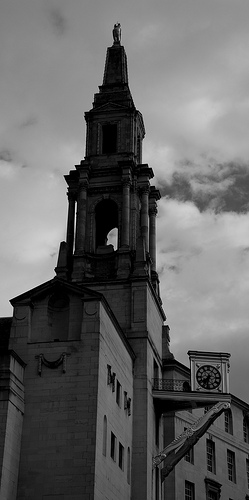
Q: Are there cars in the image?
A: No, there are no cars.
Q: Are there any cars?
A: No, there are no cars.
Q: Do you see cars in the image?
A: No, there are no cars.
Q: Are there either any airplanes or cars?
A: No, there are no cars or airplanes.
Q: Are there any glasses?
A: No, there are no glasses.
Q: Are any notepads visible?
A: No, there are no notepads.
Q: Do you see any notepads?
A: No, there are no notepads.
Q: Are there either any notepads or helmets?
A: No, there are no notepads or helmets.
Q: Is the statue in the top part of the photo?
A: Yes, the statue is in the top of the image.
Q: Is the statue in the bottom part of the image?
A: No, the statue is in the top of the image.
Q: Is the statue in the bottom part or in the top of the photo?
A: The statue is in the top of the image.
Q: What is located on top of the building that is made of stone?
A: The statue is on top of the tower.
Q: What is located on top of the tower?
A: The statue is on top of the tower.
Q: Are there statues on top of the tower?
A: Yes, there is a statue on top of the tower.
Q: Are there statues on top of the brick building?
A: Yes, there is a statue on top of the tower.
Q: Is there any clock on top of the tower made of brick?
A: No, there is a statue on top of the tower.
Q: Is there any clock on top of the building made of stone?
A: No, there is a statue on top of the tower.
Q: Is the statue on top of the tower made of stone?
A: Yes, the statue is on top of the tower.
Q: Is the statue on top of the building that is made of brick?
A: Yes, the statue is on top of the tower.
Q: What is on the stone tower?
A: The statue is on the tower.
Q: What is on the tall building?
A: The statue is on the tower.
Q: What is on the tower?
A: The statue is on the tower.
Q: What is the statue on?
A: The statue is on the tower.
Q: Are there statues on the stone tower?
A: Yes, there is a statue on the tower.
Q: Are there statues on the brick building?
A: Yes, there is a statue on the tower.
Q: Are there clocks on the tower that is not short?
A: No, there is a statue on the tower.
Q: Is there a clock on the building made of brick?
A: No, there is a statue on the tower.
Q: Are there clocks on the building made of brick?
A: No, there is a statue on the tower.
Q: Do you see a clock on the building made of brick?
A: No, there is a statue on the tower.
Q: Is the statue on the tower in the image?
A: Yes, the statue is on the tower.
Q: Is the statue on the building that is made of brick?
A: Yes, the statue is on the tower.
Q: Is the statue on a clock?
A: No, the statue is on the tower.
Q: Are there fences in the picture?
A: Yes, there is a fence.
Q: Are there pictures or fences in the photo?
A: Yes, there is a fence.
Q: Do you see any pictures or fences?
A: Yes, there is a fence.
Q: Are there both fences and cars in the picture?
A: No, there is a fence but no cars.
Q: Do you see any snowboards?
A: No, there are no snowboards.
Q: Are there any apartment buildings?
A: No, there are no apartment buildings.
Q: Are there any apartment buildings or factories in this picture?
A: No, there are no apartment buildings or factories.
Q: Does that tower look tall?
A: Yes, the tower is tall.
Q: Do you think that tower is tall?
A: Yes, the tower is tall.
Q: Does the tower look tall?
A: Yes, the tower is tall.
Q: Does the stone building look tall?
A: Yes, the tower is tall.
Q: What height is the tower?
A: The tower is tall.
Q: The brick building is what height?
A: The tower is tall.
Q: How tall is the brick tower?
A: The tower is tall.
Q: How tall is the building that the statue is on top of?
A: The tower is tall.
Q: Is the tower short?
A: No, the tower is tall.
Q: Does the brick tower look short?
A: No, the tower is tall.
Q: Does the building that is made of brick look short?
A: No, the tower is tall.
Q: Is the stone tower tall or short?
A: The tower is tall.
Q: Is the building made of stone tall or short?
A: The tower is tall.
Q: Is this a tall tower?
A: Yes, this is a tall tower.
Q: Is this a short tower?
A: No, this is a tall tower.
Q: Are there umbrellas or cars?
A: No, there are no cars or umbrellas.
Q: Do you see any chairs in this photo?
A: No, there are no chairs.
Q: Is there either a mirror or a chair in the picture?
A: No, there are no chairs or mirrors.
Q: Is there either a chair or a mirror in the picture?
A: No, there are no chairs or mirrors.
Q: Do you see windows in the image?
A: Yes, there are windows.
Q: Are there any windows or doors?
A: Yes, there are windows.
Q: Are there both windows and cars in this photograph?
A: No, there are windows but no cars.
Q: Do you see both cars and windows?
A: No, there are windows but no cars.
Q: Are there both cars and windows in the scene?
A: No, there are windows but no cars.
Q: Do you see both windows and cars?
A: No, there are windows but no cars.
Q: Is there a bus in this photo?
A: No, there are no buses.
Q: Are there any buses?
A: No, there are no buses.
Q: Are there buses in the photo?
A: No, there are no buses.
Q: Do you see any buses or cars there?
A: No, there are no buses or cars.